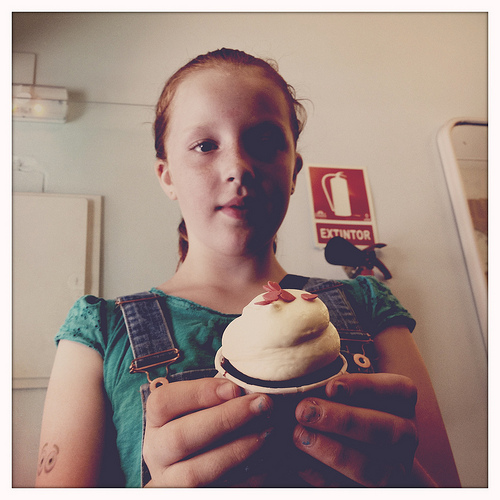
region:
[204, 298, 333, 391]
that is a cupcake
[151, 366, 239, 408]
that is a finger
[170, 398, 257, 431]
that is a finger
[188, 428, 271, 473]
that is a finger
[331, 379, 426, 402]
that is a finger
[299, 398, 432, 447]
that is a finger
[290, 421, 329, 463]
that is a finger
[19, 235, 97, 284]
that is a deep freezer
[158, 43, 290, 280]
the head of the girl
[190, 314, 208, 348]
she is wearing a green shirt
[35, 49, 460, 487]
Girl holding cupcake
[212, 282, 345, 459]
Cupcake held by girl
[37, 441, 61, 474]
Doodle on girl's arm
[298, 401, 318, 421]
Old and chipped nail polish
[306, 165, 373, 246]
Fire extinguisher sign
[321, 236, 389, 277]
Part of fire extinguisher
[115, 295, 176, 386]
Strap of girl's overalls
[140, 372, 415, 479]
Hands holding a cupcake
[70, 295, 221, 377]
Blue shirt worn by girl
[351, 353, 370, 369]
Button on strap of overalls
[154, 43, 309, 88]
Girl has reddish brown hair.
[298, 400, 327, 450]
Chipped nail polish on finger nail.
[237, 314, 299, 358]
White frosting on cupcake.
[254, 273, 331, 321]
Chocolate chip pieces on top of frosting.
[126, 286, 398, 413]
Girl wearing blue jean overhauls.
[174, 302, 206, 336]
Girl wearing green shirt.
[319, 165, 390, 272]
Red and white paper stuck on wall.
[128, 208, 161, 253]
Wall is white behind girl.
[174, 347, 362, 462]
Girl is holding cupcake.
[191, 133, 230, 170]
Girl has dark eyes.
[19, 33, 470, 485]
girl combs in a pony tail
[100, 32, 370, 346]
girl has red hair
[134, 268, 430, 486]
two hands holding a cupcake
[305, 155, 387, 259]
a red sign on white wall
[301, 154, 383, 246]
sign with has a white letter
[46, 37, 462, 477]
girl wears a green shirt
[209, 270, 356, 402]
white cream on a cupcake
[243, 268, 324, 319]
pink decorations on top the cake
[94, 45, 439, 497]
a girl holding a cupcake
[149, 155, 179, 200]
the ear of a girl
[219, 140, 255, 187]
the nose of a girl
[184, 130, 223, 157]
the eye of a girl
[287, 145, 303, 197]
the ear of a girl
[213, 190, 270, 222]
the lips of a girl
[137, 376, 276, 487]
the fingers of a hand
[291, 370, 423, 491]
the fingers of a hand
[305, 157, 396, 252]
a red and white fire extinguisher sign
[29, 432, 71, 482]
a tattoo on a girls arm